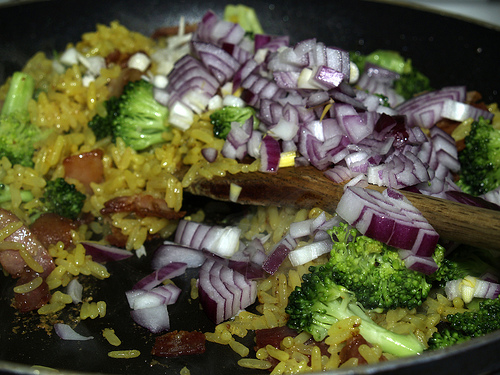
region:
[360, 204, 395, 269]
chopped purple onion on pan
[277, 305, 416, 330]
green broccoli floret in pan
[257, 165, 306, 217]
wooden spoon in pan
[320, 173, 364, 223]
wooden spoon by red onion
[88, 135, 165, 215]
yellow and oily rice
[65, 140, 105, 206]
bits of bacon in pan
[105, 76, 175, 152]
oily piece of broccoli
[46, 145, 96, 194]
bit of red tomato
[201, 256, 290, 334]
purple onion by rice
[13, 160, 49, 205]
rice is yellow and oily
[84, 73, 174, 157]
a piece of broccoli in a pan.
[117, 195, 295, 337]
chopped up onion in a pan.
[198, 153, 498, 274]
a wooden spoon in a pan.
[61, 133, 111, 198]
red pepper in a pan.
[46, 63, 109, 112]
a clump of brown rice.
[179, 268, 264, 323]
a slice of purple onion.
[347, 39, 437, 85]
a piece of broccoli.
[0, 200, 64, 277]
an oiled piece of pepper.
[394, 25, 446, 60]
a section of a frying pan.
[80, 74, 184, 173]
a light green piece of broccoli.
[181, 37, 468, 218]
purple onions in skillet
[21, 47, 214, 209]
brown rice in wok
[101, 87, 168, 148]
green broccoli in wok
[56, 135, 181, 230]
red tomatoes in wok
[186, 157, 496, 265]
brown spoon in wok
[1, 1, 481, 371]
wok is black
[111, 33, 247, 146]
white onions in black wok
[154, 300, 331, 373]
bacon stirred into rice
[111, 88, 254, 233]
brown rice is fried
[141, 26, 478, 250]
purple onions are cooking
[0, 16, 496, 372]
A rice and vegetable dish.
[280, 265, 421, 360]
A piece of broccoli.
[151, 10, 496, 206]
A pile of red onions.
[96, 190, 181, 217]
A cooked piece of meat.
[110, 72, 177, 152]
A cooked piece of broccoli.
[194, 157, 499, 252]
A wooden cooking spoon.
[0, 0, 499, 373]
A black cooking skillet.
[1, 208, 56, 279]
A piece of sausage.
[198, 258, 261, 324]
A slice of red onion.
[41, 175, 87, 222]
A small piece of broccoli.